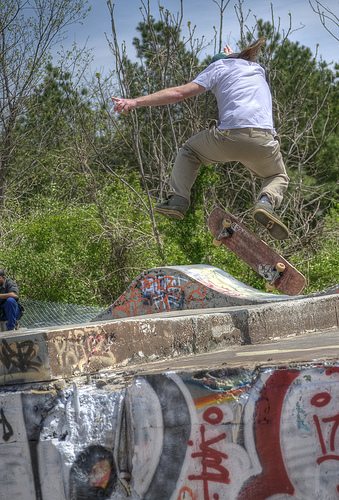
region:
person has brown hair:
[193, 47, 249, 85]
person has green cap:
[195, 40, 250, 68]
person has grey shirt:
[171, 61, 269, 132]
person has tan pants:
[155, 132, 278, 196]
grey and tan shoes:
[155, 196, 203, 230]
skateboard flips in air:
[184, 195, 307, 287]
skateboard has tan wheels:
[218, 210, 306, 288]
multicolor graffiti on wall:
[24, 397, 335, 490]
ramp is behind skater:
[112, 263, 265, 337]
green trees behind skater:
[46, 60, 337, 277]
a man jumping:
[105, 40, 336, 313]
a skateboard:
[190, 195, 315, 309]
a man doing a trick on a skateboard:
[108, 35, 315, 309]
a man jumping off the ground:
[109, 38, 324, 244]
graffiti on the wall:
[21, 362, 332, 498]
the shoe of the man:
[153, 181, 194, 224]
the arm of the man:
[95, 76, 211, 122]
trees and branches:
[11, 69, 149, 248]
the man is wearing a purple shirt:
[155, 36, 307, 242]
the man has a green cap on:
[194, 40, 278, 169]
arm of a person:
[109, 66, 224, 117]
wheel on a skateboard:
[220, 214, 231, 227]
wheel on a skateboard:
[212, 234, 223, 247]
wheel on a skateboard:
[276, 259, 288, 271]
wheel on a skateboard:
[265, 278, 274, 291]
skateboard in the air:
[204, 200, 308, 303]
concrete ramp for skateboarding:
[85, 256, 280, 323]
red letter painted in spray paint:
[200, 402, 223, 426]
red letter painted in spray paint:
[198, 424, 232, 457]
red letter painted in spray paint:
[183, 451, 232, 482]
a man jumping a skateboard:
[104, 34, 321, 300]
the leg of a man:
[158, 131, 222, 221]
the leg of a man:
[240, 158, 294, 213]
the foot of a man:
[150, 193, 190, 220]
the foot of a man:
[245, 188, 298, 240]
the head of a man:
[210, 44, 264, 70]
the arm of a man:
[111, 63, 222, 118]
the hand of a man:
[112, 91, 137, 119]